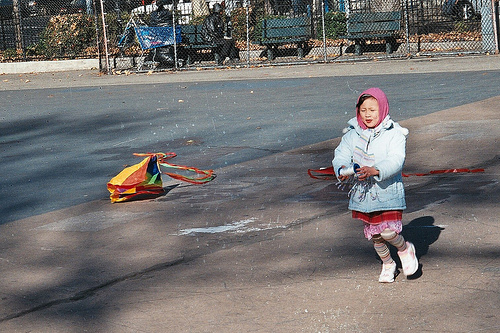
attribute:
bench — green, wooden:
[257, 13, 316, 65]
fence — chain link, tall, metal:
[8, 0, 497, 75]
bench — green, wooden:
[346, 9, 405, 55]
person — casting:
[328, 87, 427, 286]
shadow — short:
[233, 208, 445, 300]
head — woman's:
[355, 86, 393, 132]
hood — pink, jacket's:
[355, 84, 392, 132]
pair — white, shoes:
[379, 238, 421, 284]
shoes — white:
[377, 239, 421, 284]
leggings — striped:
[373, 230, 408, 266]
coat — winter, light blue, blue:
[331, 114, 411, 213]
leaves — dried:
[105, 93, 441, 262]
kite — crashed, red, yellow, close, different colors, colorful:
[104, 144, 218, 209]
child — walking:
[330, 83, 426, 288]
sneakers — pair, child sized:
[375, 242, 422, 284]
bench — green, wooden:
[137, 19, 224, 70]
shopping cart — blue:
[118, 1, 187, 69]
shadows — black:
[9, 87, 495, 318]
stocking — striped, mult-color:
[382, 226, 407, 255]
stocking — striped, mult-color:
[371, 230, 393, 266]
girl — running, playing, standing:
[327, 84, 424, 284]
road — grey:
[6, 69, 499, 329]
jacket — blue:
[328, 115, 411, 215]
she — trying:
[332, 86, 424, 284]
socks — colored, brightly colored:
[369, 224, 407, 263]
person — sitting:
[197, 2, 241, 62]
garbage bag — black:
[145, 7, 180, 27]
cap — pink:
[355, 87, 393, 130]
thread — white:
[342, 165, 357, 181]